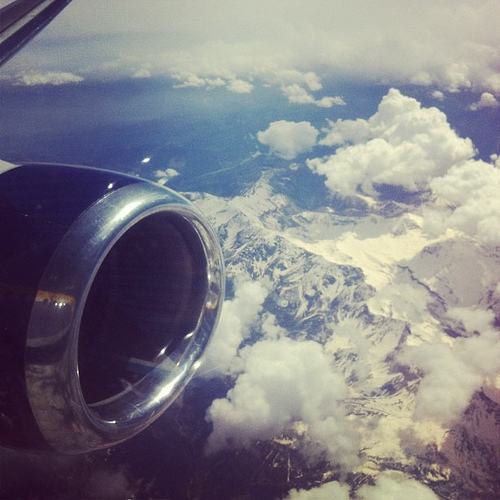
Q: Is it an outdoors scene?
A: Yes, it is outdoors.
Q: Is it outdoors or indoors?
A: It is outdoors.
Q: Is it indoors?
A: No, it is outdoors.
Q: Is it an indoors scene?
A: No, it is outdoors.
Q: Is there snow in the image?
A: Yes, there is snow.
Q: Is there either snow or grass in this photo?
A: Yes, there is snow.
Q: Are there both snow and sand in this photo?
A: No, there is snow but no sand.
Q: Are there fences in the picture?
A: No, there are no fences.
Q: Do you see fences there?
A: No, there are no fences.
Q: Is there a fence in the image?
A: No, there are no fences.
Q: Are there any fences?
A: No, there are no fences.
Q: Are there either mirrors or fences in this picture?
A: No, there are no fences or mirrors.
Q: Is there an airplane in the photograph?
A: Yes, there is an airplane.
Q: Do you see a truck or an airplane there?
A: Yes, there is an airplane.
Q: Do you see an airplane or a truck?
A: Yes, there is an airplane.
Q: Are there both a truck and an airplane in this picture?
A: No, there is an airplane but no trucks.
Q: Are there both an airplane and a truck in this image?
A: No, there is an airplane but no trucks.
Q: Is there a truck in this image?
A: No, there are no trucks.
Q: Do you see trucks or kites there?
A: No, there are no trucks or kites.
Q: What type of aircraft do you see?
A: The aircraft is an airplane.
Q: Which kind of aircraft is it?
A: The aircraft is an airplane.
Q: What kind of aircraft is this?
A: That is an airplane.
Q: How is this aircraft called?
A: That is an airplane.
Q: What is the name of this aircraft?
A: That is an airplane.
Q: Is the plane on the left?
A: Yes, the plane is on the left of the image.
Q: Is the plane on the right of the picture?
A: No, the plane is on the left of the image.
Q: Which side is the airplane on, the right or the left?
A: The airplane is on the left of the image.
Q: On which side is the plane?
A: The plane is on the left of the image.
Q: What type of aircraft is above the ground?
A: The aircraft is an airplane.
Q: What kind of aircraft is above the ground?
A: The aircraft is an airplane.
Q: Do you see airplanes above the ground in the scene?
A: Yes, there is an airplane above the ground.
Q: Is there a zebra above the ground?
A: No, there is an airplane above the ground.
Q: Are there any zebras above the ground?
A: No, there is an airplane above the ground.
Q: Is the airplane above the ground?
A: Yes, the airplane is above the ground.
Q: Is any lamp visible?
A: No, there are no lamps.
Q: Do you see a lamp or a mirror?
A: No, there are no lamps or mirrors.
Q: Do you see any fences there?
A: No, there are no fences.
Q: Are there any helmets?
A: No, there are no helmets.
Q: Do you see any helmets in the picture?
A: No, there are no helmets.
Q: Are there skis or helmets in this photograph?
A: No, there are no helmets or skis.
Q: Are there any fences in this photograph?
A: No, there are no fences.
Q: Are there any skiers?
A: No, there are no skiers.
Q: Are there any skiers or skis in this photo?
A: No, there are no skiers or skis.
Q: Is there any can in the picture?
A: No, there are no cans.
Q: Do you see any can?
A: No, there are no cans.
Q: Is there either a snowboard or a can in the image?
A: No, there are no cans or snowboards.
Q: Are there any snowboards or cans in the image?
A: No, there are no cans or snowboards.